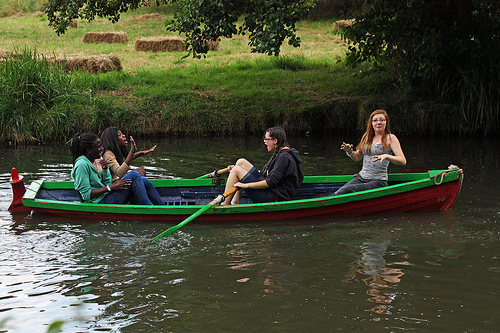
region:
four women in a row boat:
[1, 99, 464, 227]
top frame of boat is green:
[27, 182, 433, 217]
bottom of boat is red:
[308, 183, 457, 208]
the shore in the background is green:
[155, 49, 265, 142]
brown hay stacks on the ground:
[80, 27, 183, 69]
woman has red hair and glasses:
[335, 99, 398, 201]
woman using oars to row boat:
[152, 122, 307, 250]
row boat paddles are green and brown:
[152, 186, 244, 253]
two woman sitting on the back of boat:
[14, 123, 161, 218]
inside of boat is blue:
[46, 184, 326, 201]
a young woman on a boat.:
[318, 94, 420, 208]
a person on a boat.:
[207, 105, 301, 222]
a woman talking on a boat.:
[101, 121, 176, 209]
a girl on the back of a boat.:
[56, 114, 124, 202]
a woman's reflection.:
[334, 225, 443, 327]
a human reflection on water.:
[212, 231, 312, 329]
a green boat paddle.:
[141, 185, 240, 254]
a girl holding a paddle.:
[190, 148, 250, 180]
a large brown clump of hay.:
[0, 41, 142, 88]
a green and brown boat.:
[6, 154, 478, 237]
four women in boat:
[12, 102, 459, 224]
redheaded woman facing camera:
[333, 106, 408, 203]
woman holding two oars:
[202, 120, 304, 224]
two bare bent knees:
[225, 154, 257, 191]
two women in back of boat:
[67, 123, 160, 211]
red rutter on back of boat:
[3, 162, 32, 219]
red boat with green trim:
[399, 173, 433, 213]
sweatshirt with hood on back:
[262, 140, 310, 200]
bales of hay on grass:
[71, 25, 218, 56]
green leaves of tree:
[249, 8, 289, 40]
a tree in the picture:
[65, 132, 116, 208]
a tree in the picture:
[216, 123, 307, 196]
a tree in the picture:
[337, 107, 410, 184]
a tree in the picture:
[103, 122, 149, 174]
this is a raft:
[23, 162, 462, 216]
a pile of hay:
[72, 50, 126, 73]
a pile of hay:
[78, 21, 128, 51]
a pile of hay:
[133, 35, 193, 57]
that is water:
[266, 251, 471, 318]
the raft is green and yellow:
[24, 157, 471, 216]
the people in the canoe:
[65, 102, 417, 210]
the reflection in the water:
[209, 235, 435, 327]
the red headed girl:
[340, 104, 399, 196]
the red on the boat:
[389, 190, 449, 212]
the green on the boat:
[422, 167, 438, 184]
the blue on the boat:
[168, 186, 203, 200]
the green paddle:
[151, 205, 213, 260]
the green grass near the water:
[152, 50, 292, 118]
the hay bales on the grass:
[50, 24, 190, 72]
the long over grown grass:
[3, 40, 77, 129]